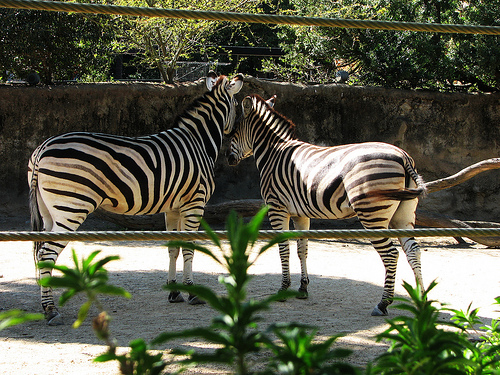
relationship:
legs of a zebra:
[267, 212, 343, 307] [186, 49, 440, 286]